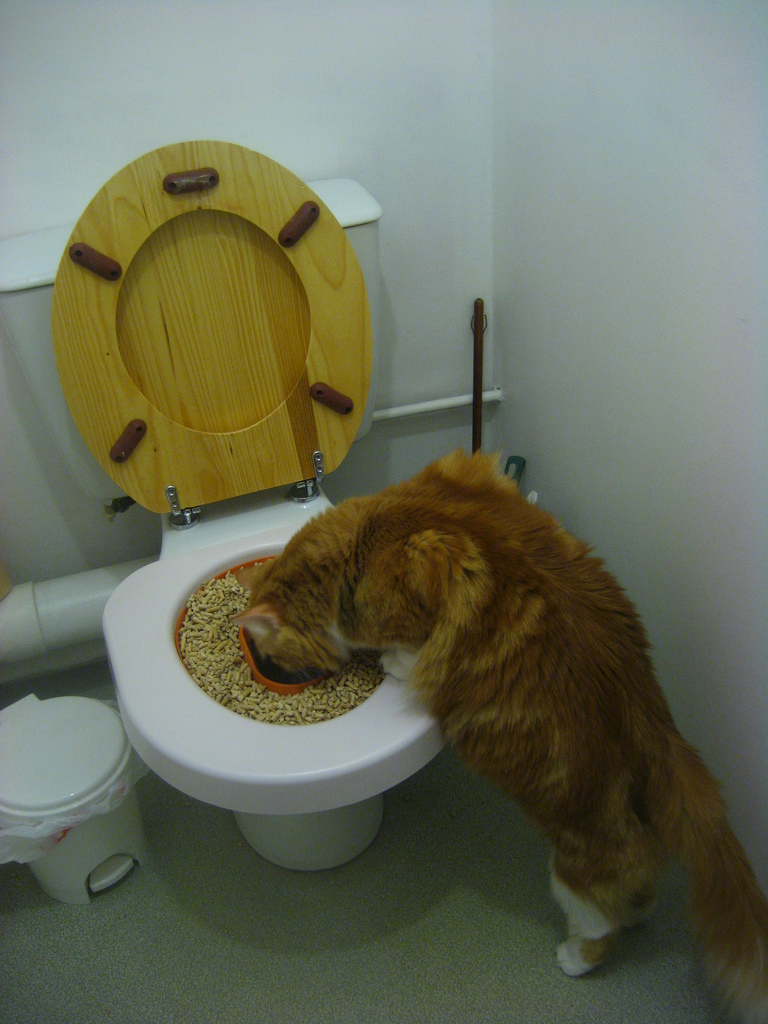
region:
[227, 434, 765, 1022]
the cat is color brown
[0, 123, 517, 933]
front body of cat in a toilet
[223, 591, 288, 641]
pointy ear of cat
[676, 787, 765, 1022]
the tail is brown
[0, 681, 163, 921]
the trash can is white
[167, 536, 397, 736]
food in a toilet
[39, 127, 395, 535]
the lid of a toilet is brown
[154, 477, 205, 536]
the hinge is color silver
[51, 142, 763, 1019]
cat eating out of the toilet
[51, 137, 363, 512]
brown wooden toilet seat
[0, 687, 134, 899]
closed trash can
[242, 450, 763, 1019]
brown and white cat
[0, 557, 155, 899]
pipe behind trash can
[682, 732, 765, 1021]
long furry cat tail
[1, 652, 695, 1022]
clean pale green floor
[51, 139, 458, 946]
shadow beneath toilet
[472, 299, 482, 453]
thin and long handle behind cat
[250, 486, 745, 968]
a large orange hairy cat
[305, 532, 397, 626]
the neck of a cat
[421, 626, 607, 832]
the belly of a cat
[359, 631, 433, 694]
the front paw of a cat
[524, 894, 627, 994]
the back paw of a cat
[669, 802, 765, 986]
the tail of a cat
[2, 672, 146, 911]
a small white trashcan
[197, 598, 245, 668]
a bunch of kitty litter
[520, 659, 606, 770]
fur of the dog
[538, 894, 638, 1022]
legs on the floor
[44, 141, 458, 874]
toilet filled with cat litter and cat food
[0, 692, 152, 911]
waste paper basket in bathroom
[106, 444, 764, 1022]
cat eating out of a toilet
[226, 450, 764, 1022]
orange and white cat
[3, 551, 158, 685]
white pvc pipe in bathroom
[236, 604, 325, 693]
container cat is eating out of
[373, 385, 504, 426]
small pipe coming in through the bathroom wall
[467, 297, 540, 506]
handles of cleaning instruments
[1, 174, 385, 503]
toilet tank for water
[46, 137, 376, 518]
toilet seat of wood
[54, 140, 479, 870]
toilet bowl full of cat food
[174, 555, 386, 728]
dried food in orange container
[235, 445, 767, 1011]
orange cat standing on two feet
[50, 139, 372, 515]
underside of raised wood toilet seat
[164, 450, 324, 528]
silver metal hinges of toilet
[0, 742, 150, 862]
edge of plastic trash bag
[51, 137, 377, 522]
toilet seat made of wood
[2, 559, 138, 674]
white pvc piping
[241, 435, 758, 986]
a large orange cat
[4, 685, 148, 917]
a small white trash can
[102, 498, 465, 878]
a toilet containing cat food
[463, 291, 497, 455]
a black handle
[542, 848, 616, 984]
white patch on cats foot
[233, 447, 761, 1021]
an orange and white cat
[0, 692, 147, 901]
a small plasic trash can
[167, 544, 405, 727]
an orange cat toilet trainer tray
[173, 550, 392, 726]
an orange tray filled with cat litter pellets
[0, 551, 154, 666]
a length of pvc pipe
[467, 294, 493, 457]
a wooden handle with a strap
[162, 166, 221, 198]
a brown plastic toilet seat bumper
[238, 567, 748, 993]
Cat eating out white toilet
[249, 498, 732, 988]
Orange cat eating out toilet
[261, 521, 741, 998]
Orange cat eating out white toilet